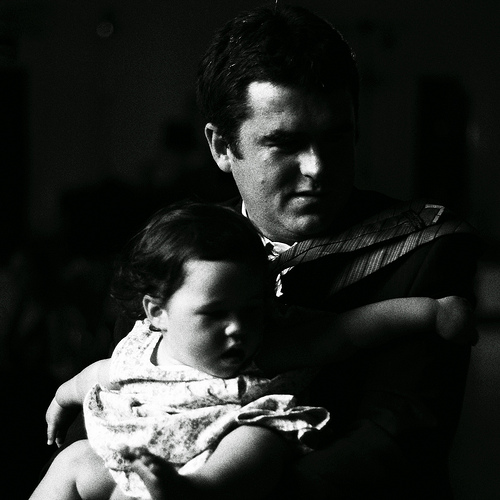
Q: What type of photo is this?
A: Black and white.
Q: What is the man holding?
A: Baby.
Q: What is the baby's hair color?
A: Black.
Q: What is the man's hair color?
A: Black.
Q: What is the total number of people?
A: 2.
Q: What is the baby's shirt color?
A: White.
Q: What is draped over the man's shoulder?
A: Tie.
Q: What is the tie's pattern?
A: Striped.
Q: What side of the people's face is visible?
A: Right.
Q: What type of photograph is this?
A: Black and white.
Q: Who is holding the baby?
A: A man.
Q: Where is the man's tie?
A: Thrown over shoulder.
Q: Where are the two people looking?
A: Off to the right.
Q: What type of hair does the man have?
A: Short dark hair.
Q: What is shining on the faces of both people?
A: Light.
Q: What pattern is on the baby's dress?
A: Floral.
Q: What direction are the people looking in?
A: Left.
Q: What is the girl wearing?
A: Dress.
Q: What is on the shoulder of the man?
A: A tie.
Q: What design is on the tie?
A: Stripes.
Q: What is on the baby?
A: A dress.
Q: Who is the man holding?
A: A baby.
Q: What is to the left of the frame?
A: The babies arm.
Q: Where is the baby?
A: In the man's arms.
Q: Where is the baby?
A: In his arm.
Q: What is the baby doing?
A: Staring at something.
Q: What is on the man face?
A: Looks like a bump.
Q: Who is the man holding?
A: The baby.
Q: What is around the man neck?
A: His tie.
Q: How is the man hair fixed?
A: Short and black.